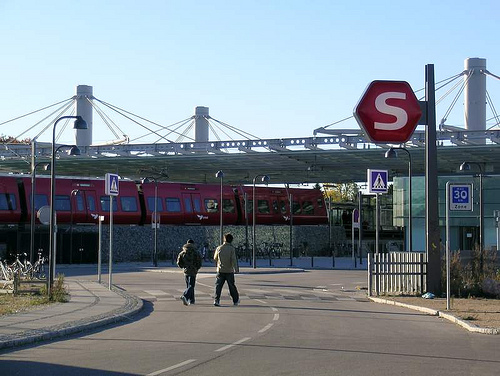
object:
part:
[274, 345, 340, 353]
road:
[3, 259, 499, 374]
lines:
[143, 353, 200, 376]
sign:
[349, 76, 431, 150]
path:
[0, 259, 145, 351]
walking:
[166, 281, 204, 308]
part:
[230, 257, 241, 265]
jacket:
[211, 242, 242, 276]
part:
[218, 22, 273, 45]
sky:
[0, 1, 500, 144]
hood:
[221, 241, 235, 247]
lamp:
[43, 115, 87, 305]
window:
[162, 194, 183, 215]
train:
[0, 170, 336, 228]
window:
[256, 197, 270, 215]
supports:
[70, 80, 99, 150]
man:
[205, 220, 247, 312]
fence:
[360, 247, 437, 300]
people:
[164, 225, 212, 307]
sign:
[441, 177, 477, 213]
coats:
[172, 243, 206, 276]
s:
[367, 82, 416, 136]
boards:
[45, 326, 63, 342]